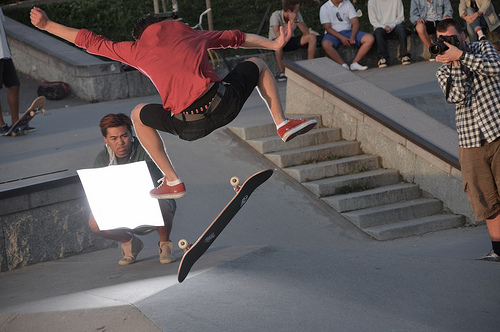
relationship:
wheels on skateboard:
[171, 169, 241, 250] [157, 155, 277, 277]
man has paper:
[71, 97, 189, 277] [71, 157, 171, 238]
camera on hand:
[427, 34, 457, 59] [433, 37, 465, 67]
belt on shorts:
[160, 74, 231, 123] [137, 57, 264, 145]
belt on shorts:
[160, 74, 231, 123] [456, 134, 499, 226]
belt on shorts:
[160, 74, 231, 123] [268, 30, 304, 51]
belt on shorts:
[160, 74, 231, 123] [323, 29, 368, 47]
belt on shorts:
[160, 74, 231, 123] [414, 16, 440, 37]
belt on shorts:
[160, 74, 231, 123] [1, 55, 21, 94]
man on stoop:
[320, 0, 375, 71] [274, 24, 494, 55]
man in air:
[85, 113, 173, 264] [4, 3, 498, 132]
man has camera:
[411, 14, 496, 260] [424, 33, 459, 60]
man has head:
[85, 113, 173, 264] [102, 117, 134, 157]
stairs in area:
[227, 112, 464, 239] [1, 56, 498, 329]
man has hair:
[85, 113, 173, 264] [101, 112, 135, 135]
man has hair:
[411, 14, 496, 260] [432, 12, 481, 37]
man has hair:
[320, 0, 375, 71] [101, 112, 135, 135]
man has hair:
[266, 1, 314, 82] [101, 112, 135, 135]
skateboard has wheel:
[145, 162, 294, 282] [174, 234, 189, 252]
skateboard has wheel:
[145, 162, 294, 282] [229, 171, 242, 190]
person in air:
[26, 4, 323, 198] [3, 2, 498, 183]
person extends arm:
[26, 4, 323, 198] [27, 6, 134, 63]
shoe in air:
[273, 114, 322, 141] [3, 2, 498, 183]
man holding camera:
[411, 14, 496, 260] [415, 19, 498, 234]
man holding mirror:
[429, 15, 499, 270] [74, 162, 170, 247]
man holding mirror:
[85, 113, 173, 264] [79, 162, 166, 229]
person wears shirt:
[26, 4, 323, 198] [70, 19, 248, 115]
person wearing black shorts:
[26, 4, 323, 198] [138, 59, 260, 140]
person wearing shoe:
[26, 4, 323, 198] [270, 115, 321, 142]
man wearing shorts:
[411, 14, 496, 260] [456, 144, 497, 218]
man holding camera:
[411, 14, 496, 260] [424, 30, 462, 57]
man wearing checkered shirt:
[429, 15, 499, 270] [432, 40, 499, 148]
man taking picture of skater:
[411, 14, 496, 260] [156, 163, 273, 263]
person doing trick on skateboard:
[56, 11, 309, 193] [114, 137, 329, 307]